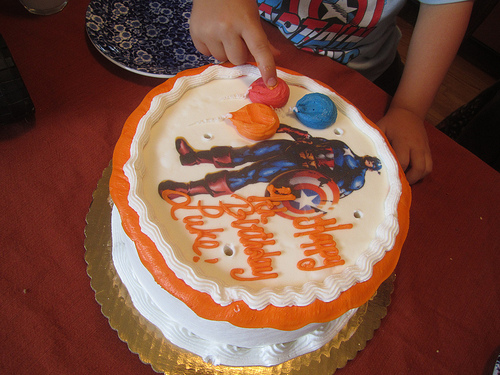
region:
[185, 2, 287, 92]
a finger touching icing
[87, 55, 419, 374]
a orange and white birthday cake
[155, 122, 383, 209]
action hero on a cake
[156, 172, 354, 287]
writing on a birthday cake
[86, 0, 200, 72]
a blue plate with flowers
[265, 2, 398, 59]
a red white and blue shirt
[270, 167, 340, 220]
a red white and blue battle shield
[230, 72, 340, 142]
red blue and orange frosting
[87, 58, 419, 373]
birthday cake on a gold platter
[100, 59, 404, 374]
birthday cake with four holes in the top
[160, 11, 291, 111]
Child places pointer finger in cake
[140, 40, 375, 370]
Happy birthday cake in photo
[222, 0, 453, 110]
Child in photo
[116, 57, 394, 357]
Captian America cake in photo with orange border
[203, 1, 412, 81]
Captain America shirt on child in photo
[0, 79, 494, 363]
Table with read table cloth in photo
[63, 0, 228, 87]
Black and white flowered plates in photo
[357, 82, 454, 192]
Child has hand placed on table in photo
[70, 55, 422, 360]
Cake is sitting on gold plate in photo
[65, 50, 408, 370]
Three different color ballons in photo.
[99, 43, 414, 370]
birthday cake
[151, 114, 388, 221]
design of captain america on a cake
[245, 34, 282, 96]
finger touching the cake's icing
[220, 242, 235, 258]
hole where candle was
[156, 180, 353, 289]
writing in orange icing on cake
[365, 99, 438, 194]
hand resting on the table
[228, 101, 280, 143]
orange ball of frosting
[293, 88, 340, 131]
blue ball of frosting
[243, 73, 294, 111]
red ball of frosting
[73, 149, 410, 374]
gold cake platter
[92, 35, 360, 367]
A cake is visible.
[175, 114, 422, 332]
A cake is visible.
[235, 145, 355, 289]
A cake is visible.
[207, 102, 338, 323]
A cake is visible.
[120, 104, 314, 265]
A cake is visible.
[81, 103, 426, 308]
a round 9 inch cake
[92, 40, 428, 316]
the cake is white with orange trim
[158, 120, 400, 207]
the cake has captain america on top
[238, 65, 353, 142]
the cake has 3 colorful balloons on it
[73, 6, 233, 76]
a blue and white patterned plate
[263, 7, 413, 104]
the child is wearing a captain america shirt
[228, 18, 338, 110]
the child's finger is on the red balloon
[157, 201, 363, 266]
the cake is for Luke's birthday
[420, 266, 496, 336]
the cake is on A red table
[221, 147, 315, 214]
Luke is 4 years old